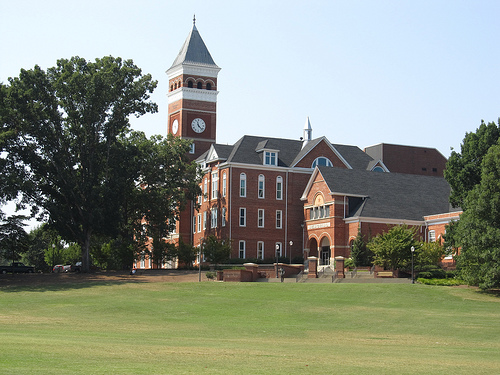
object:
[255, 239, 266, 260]
windows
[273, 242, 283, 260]
windows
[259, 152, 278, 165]
window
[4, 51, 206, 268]
tree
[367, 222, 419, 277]
tree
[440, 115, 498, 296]
tree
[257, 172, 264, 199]
window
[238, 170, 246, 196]
window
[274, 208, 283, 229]
window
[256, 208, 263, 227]
window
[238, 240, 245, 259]
window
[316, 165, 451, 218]
house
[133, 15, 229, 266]
building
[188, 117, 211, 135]
clock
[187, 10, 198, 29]
cross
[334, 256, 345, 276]
column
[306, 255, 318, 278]
column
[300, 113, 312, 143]
steeple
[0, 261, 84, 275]
cars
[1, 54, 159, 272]
tree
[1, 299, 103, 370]
lawn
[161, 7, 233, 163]
clock tower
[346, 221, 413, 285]
tree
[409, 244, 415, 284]
lamp post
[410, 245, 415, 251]
white shade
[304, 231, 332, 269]
arched doorways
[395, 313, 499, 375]
lawn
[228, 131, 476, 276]
building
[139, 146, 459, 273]
church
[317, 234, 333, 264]
doorway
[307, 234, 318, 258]
doorway